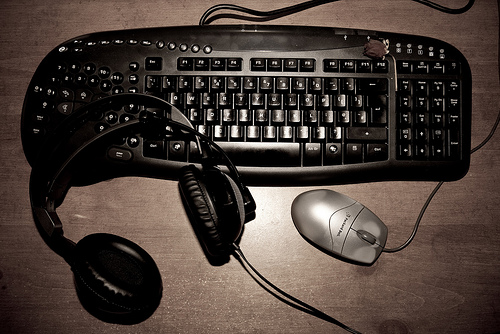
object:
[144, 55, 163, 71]
escape key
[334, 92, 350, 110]
keys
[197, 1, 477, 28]
black cord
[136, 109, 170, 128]
microphone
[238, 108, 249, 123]
key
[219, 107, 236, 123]
key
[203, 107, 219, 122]
key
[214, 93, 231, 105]
key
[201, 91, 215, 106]
key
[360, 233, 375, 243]
wheel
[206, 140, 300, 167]
spacebar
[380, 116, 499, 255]
cord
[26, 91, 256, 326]
headphones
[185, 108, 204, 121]
keys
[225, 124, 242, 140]
keys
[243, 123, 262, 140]
keys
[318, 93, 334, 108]
keys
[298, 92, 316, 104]
keys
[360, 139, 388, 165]
keys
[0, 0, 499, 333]
desk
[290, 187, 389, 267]
grey mouse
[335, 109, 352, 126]
keys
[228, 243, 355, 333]
cord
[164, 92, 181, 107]
keys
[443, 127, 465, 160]
keys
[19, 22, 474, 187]
keyboard